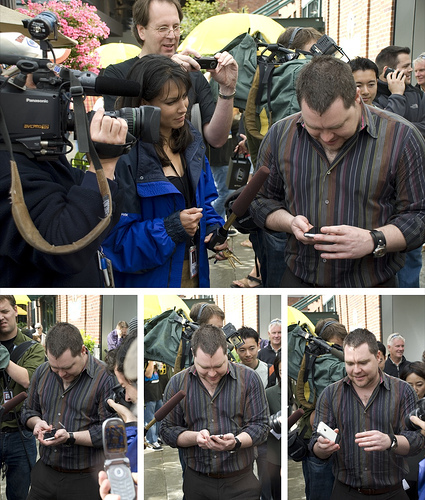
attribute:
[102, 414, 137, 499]
flip phone — outdated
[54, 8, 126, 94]
flowers — pink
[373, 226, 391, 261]
wristwatch — black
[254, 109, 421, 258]
shirt — gray, stripe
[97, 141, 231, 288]
coat — blue colored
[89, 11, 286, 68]
umbrellas — yellow, set up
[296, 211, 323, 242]
phone — flip, opened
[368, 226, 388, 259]
wrist watch — men's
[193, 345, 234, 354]
hairline — receding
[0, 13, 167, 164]
camera — black, news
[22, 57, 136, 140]
camera — TV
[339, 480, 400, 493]
belt — brown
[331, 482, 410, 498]
pants — brown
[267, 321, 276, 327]
hair — grey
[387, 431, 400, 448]
band — black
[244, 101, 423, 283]
shirt — striped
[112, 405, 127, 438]
jacket — blue